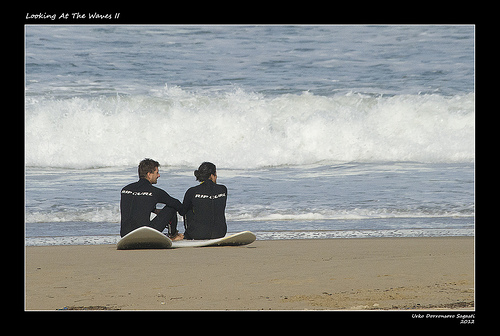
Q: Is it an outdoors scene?
A: Yes, it is outdoors.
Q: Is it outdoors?
A: Yes, it is outdoors.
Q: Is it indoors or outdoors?
A: It is outdoors.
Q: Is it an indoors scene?
A: No, it is outdoors.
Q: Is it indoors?
A: No, it is outdoors.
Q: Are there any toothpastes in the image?
A: No, there are no toothpastes.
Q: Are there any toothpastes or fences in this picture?
A: No, there are no toothpastes or fences.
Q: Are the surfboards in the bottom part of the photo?
A: Yes, the surfboards are in the bottom of the image.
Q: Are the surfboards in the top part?
A: No, the surfboards are in the bottom of the image.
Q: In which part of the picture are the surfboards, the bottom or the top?
A: The surfboards are in the bottom of the image.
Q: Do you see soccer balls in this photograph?
A: No, there are no soccer balls.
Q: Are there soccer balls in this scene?
A: No, there are no soccer balls.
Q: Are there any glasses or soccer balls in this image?
A: No, there are no soccer balls or glasses.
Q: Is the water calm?
A: Yes, the water is calm.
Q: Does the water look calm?
A: Yes, the water is calm.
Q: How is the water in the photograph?
A: The water is calm.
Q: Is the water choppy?
A: No, the water is calm.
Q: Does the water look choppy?
A: No, the water is calm.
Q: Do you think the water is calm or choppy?
A: The water is calm.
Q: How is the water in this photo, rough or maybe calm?
A: The water is calm.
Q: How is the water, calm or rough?
A: The water is calm.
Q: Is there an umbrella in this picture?
A: No, there are no umbrellas.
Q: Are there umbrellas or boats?
A: No, there are no umbrellas or boats.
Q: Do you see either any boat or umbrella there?
A: No, there are no umbrellas or boats.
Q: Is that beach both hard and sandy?
A: Yes, the beach is hard and sandy.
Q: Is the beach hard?
A: Yes, the beach is hard.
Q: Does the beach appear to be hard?
A: Yes, the beach is hard.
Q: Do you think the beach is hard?
A: Yes, the beach is hard.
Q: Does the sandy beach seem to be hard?
A: Yes, the beach is hard.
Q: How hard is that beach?
A: The beach is hard.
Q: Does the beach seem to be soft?
A: No, the beach is hard.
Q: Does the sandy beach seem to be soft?
A: No, the beach is hard.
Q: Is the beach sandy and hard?
A: Yes, the beach is sandy and hard.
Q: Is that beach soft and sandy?
A: No, the beach is sandy but hard.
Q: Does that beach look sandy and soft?
A: No, the beach is sandy but hard.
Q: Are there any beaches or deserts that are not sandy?
A: No, there is a beach but it is sandy.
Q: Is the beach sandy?
A: Yes, the beach is sandy.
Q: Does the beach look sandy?
A: Yes, the beach is sandy.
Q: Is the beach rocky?
A: No, the beach is sandy.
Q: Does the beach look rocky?
A: No, the beach is sandy.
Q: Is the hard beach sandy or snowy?
A: The beach is sandy.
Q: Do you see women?
A: Yes, there is a woman.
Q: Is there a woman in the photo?
A: Yes, there is a woman.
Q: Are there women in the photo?
A: Yes, there is a woman.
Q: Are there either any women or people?
A: Yes, there is a woman.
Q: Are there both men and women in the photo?
A: Yes, there are both a woman and a man.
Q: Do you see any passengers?
A: No, there are no passengers.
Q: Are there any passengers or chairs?
A: No, there are no passengers or chairs.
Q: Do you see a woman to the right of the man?
A: Yes, there is a woman to the right of the man.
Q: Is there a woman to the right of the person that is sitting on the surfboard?
A: Yes, there is a woman to the right of the man.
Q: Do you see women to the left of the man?
A: No, the woman is to the right of the man.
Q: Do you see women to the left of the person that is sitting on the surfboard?
A: No, the woman is to the right of the man.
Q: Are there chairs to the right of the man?
A: No, there is a woman to the right of the man.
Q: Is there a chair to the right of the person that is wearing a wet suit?
A: No, there is a woman to the right of the man.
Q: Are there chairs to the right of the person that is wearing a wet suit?
A: No, there is a woman to the right of the man.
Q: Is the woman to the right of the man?
A: Yes, the woman is to the right of the man.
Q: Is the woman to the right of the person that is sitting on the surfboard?
A: Yes, the woman is to the right of the man.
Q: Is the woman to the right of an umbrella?
A: No, the woman is to the right of the man.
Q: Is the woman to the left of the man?
A: No, the woman is to the right of the man.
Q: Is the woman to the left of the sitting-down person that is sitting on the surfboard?
A: No, the woman is to the right of the man.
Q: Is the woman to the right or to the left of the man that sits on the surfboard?
A: The woman is to the right of the man.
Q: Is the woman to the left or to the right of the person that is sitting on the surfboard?
A: The woman is to the right of the man.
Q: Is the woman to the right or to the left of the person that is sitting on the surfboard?
A: The woman is to the right of the man.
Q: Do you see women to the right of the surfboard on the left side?
A: Yes, there is a woman to the right of the surfboard.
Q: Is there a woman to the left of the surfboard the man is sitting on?
A: No, the woman is to the right of the surfboard.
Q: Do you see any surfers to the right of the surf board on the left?
A: No, there is a woman to the right of the surf board.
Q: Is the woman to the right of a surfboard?
A: Yes, the woman is to the right of a surfboard.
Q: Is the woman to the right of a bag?
A: No, the woman is to the right of a surfboard.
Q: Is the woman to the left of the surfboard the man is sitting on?
A: No, the woman is to the right of the surfboard.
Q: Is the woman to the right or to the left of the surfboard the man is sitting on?
A: The woman is to the right of the surfboard.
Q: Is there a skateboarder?
A: No, there are no skateboarders.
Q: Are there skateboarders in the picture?
A: No, there are no skateboarders.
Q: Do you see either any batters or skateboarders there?
A: No, there are no skateboarders or batters.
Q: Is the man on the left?
A: Yes, the man is on the left of the image.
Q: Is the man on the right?
A: No, the man is on the left of the image.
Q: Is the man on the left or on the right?
A: The man is on the left of the image.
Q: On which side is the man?
A: The man is on the left of the image.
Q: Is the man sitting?
A: Yes, the man is sitting.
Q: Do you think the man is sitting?
A: Yes, the man is sitting.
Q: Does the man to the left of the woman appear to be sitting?
A: Yes, the man is sitting.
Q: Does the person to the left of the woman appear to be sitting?
A: Yes, the man is sitting.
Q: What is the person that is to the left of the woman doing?
A: The man is sitting.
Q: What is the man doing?
A: The man is sitting.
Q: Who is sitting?
A: The man is sitting.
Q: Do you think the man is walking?
A: No, the man is sitting.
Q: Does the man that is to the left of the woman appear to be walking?
A: No, the man is sitting.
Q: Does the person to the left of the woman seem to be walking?
A: No, the man is sitting.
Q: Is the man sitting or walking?
A: The man is sitting.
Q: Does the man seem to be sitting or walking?
A: The man is sitting.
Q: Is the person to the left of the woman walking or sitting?
A: The man is sitting.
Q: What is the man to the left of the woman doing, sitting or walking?
A: The man is sitting.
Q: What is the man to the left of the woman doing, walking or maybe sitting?
A: The man is sitting.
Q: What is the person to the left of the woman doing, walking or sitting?
A: The man is sitting.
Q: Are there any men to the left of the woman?
A: Yes, there is a man to the left of the woman.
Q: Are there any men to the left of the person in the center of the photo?
A: Yes, there is a man to the left of the woman.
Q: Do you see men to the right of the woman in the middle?
A: No, the man is to the left of the woman.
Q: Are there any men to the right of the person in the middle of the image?
A: No, the man is to the left of the woman.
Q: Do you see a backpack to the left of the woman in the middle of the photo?
A: No, there is a man to the left of the woman.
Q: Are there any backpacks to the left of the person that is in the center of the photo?
A: No, there is a man to the left of the woman.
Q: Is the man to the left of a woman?
A: Yes, the man is to the left of a woman.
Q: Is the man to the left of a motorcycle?
A: No, the man is to the left of a woman.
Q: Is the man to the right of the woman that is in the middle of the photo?
A: No, the man is to the left of the woman.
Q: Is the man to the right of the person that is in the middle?
A: No, the man is to the left of the woman.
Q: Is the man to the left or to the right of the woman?
A: The man is to the left of the woman.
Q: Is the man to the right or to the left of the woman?
A: The man is to the left of the woman.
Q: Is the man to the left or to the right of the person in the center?
A: The man is to the left of the woman.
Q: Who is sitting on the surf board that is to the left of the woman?
A: The man is sitting on the surfboard.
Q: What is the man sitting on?
A: The man is sitting on the surfboard.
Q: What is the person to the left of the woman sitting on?
A: The man is sitting on the surfboard.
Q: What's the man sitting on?
A: The man is sitting on the surfboard.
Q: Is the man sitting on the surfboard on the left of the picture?
A: Yes, the man is sitting on the surfboard.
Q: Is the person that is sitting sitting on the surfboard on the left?
A: Yes, the man is sitting on the surfboard.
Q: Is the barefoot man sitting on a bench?
A: No, the man is sitting on the surfboard.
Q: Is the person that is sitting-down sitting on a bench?
A: No, the man is sitting on the surfboard.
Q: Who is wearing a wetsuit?
A: The man is wearing a wetsuit.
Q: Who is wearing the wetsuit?
A: The man is wearing a wetsuit.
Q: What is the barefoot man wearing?
A: The man is wearing a wetsuit.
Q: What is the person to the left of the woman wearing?
A: The man is wearing a wetsuit.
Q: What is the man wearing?
A: The man is wearing a wetsuit.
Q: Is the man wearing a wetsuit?
A: Yes, the man is wearing a wetsuit.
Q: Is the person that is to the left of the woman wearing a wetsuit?
A: Yes, the man is wearing a wetsuit.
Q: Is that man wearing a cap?
A: No, the man is wearing a wetsuit.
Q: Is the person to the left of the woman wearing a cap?
A: No, the man is wearing a wetsuit.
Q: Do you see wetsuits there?
A: Yes, there is a wetsuit.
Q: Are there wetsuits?
A: Yes, there is a wetsuit.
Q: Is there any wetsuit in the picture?
A: Yes, there is a wetsuit.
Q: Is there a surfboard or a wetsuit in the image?
A: Yes, there is a wetsuit.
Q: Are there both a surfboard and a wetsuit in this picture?
A: Yes, there are both a wetsuit and a surfboard.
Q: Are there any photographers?
A: Yes, there is a photographer.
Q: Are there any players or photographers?
A: Yes, there is a photographer.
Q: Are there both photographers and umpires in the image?
A: No, there is a photographer but no umpires.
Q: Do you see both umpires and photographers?
A: No, there is a photographer but no umpires.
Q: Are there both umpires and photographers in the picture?
A: No, there is a photographer but no umpires.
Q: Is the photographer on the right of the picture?
A: Yes, the photographer is on the right of the image.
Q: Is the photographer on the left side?
A: No, the photographer is on the right of the image.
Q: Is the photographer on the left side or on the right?
A: The photographer is on the right of the image.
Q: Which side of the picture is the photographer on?
A: The photographer is on the right of the image.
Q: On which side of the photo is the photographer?
A: The photographer is on the right of the image.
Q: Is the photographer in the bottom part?
A: Yes, the photographer is in the bottom of the image.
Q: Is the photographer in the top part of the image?
A: No, the photographer is in the bottom of the image.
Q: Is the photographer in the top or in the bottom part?
A: The photographer is in the bottom of the image.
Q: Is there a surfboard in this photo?
A: Yes, there is a surfboard.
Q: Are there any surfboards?
A: Yes, there is a surfboard.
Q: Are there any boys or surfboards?
A: Yes, there is a surfboard.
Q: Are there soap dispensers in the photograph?
A: No, there are no soap dispensers.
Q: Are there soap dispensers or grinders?
A: No, there are no soap dispensers or grinders.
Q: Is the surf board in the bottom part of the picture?
A: Yes, the surf board is in the bottom of the image.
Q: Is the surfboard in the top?
A: No, the surfboard is in the bottom of the image.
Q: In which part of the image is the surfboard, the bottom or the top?
A: The surfboard is in the bottom of the image.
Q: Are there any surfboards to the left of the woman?
A: Yes, there is a surfboard to the left of the woman.